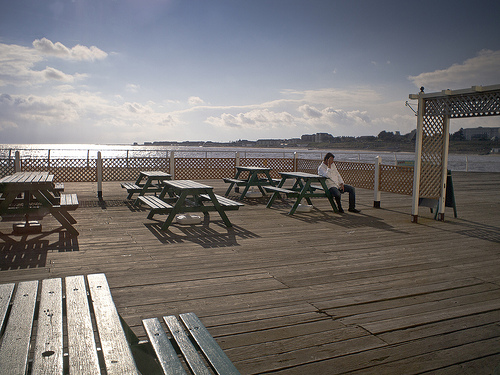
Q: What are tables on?
A: A large wooden deck.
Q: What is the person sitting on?
A: A picnic table.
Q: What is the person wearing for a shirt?
A: A white long sleeved shirt.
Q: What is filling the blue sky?
A: White clouds.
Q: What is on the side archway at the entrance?
A: Lattice work.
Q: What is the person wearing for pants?
A: Blue jeans.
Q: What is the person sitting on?
A: A picnic table.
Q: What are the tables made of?
A: Wood.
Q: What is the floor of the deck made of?
A: Wood.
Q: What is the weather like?
A: Sunny and partly cloudy.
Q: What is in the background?
A: A body of water with buildings in the back.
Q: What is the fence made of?
A: Wood.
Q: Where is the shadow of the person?
A: In front of him.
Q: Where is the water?
A: Behind the person sitting down.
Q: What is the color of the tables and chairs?
A: Green.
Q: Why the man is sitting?
A: Resting.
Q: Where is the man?
A: Sitting.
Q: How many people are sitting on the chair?
A: One.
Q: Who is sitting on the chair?
A: A man.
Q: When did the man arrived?
A: Earlier.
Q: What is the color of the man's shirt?
A: White.